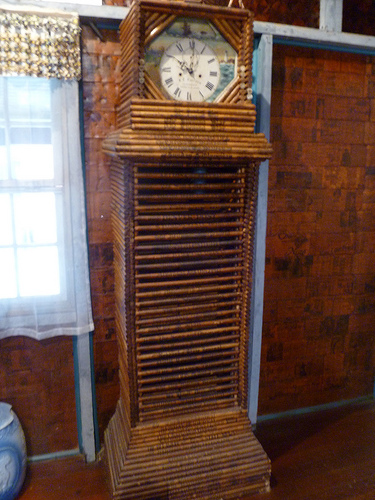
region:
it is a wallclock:
[133, 4, 249, 105]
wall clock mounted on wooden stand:
[110, 2, 275, 495]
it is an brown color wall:
[293, 71, 357, 348]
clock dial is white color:
[160, 33, 222, 103]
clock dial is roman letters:
[160, 35, 223, 99]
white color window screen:
[9, 88, 92, 339]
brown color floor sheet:
[281, 429, 371, 489]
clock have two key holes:
[176, 65, 209, 85]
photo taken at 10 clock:
[146, 13, 246, 106]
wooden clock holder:
[109, 1, 263, 498]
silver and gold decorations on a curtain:
[0, 19, 80, 64]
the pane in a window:
[13, 191, 58, 244]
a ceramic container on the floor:
[0, 398, 21, 496]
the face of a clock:
[147, 18, 241, 105]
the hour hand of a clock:
[170, 52, 188, 73]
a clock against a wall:
[107, 2, 311, 467]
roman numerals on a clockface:
[173, 83, 194, 102]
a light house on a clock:
[219, 47, 236, 73]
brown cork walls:
[290, 142, 359, 272]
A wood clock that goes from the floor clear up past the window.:
[104, 3, 269, 499]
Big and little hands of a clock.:
[165, 51, 196, 77]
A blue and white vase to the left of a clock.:
[0, 398, 27, 498]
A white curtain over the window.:
[0, 73, 95, 339]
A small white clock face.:
[161, 38, 218, 102]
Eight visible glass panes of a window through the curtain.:
[0, 75, 59, 300]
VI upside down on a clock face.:
[184, 90, 192, 102]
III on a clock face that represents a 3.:
[208, 69, 218, 78]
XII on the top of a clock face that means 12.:
[187, 38, 195, 52]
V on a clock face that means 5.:
[197, 89, 204, 98]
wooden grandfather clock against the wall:
[98, 0, 267, 496]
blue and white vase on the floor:
[0, 402, 27, 498]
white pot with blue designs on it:
[0, 401, 28, 496]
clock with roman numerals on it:
[158, 37, 219, 101]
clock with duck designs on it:
[140, 16, 241, 103]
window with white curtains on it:
[0, 7, 93, 336]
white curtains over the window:
[0, 6, 96, 336]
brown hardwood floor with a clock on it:
[10, 400, 374, 499]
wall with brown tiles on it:
[0, 0, 372, 497]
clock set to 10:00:
[159, 36, 222, 104]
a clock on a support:
[100, 0, 280, 498]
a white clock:
[153, 31, 228, 103]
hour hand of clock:
[170, 52, 191, 77]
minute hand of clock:
[185, 42, 198, 74]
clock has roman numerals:
[155, 31, 224, 106]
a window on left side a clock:
[2, 3, 263, 331]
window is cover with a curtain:
[4, 6, 101, 343]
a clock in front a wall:
[11, 3, 367, 494]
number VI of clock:
[181, 89, 196, 104]